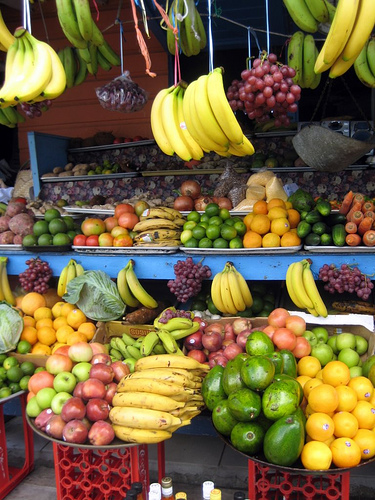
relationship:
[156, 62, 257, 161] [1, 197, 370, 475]
bananas hanging above fruit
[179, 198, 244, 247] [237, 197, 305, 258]
fruit next to oranges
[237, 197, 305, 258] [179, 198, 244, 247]
oranges next to fruit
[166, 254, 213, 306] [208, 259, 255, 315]
grapes next to bananas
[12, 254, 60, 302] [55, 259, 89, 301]
grapes next to bananas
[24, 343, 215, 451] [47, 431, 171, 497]
fruit on crate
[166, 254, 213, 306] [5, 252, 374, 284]
grapes hang from wood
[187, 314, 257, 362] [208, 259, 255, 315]
apples in front of bananas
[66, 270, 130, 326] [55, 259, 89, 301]
vegetable in between bananas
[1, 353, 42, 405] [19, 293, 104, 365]
limes under oranges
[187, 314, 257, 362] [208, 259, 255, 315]
apples near bananas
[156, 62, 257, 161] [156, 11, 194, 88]
bananas hang from string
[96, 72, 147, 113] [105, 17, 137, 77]
bags of grapes hang from string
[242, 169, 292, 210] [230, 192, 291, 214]
lemons sit on tray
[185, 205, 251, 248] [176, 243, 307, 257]
limes sit on tray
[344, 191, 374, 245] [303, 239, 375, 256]
carrots on tray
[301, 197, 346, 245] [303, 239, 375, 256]
cucumber on tray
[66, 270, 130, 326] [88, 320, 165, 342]
cabbage on box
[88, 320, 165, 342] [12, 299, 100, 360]
box of lemons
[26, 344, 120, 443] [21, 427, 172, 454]
apples sit on tray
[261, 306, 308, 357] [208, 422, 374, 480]
onions sit on tray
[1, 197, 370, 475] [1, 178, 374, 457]
fruit on display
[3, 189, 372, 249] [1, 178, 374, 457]
vegetables on display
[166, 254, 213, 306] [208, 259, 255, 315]
grapes with bananas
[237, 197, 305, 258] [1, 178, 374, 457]
oranges on display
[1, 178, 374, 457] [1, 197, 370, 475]
collection of fruits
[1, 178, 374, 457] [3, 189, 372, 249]
collection of vegetables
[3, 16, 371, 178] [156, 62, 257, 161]
collection of bananas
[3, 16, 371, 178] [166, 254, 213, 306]
collection of grapes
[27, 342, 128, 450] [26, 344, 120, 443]
assortment of apples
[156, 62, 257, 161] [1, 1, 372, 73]
bananas hang from ceiling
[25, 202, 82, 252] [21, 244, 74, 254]
avocado over a container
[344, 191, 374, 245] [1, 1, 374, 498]
carrots are in photo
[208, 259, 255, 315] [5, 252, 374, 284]
bananas hang from table